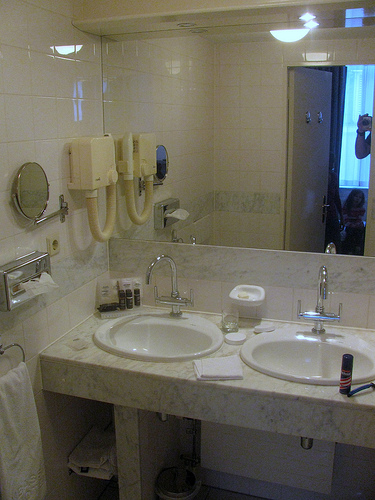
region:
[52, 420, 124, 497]
a folded towel on a shelf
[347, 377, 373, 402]
a blue razor on a bathroom counter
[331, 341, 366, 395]
a small container of shave cream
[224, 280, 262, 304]
a bar of soap in a soap dish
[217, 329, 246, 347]
a bar of soap on a bathroom counter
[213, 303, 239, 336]
a clear drinking glass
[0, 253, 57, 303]
a paper towel dispenser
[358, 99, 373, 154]
the reflection of someone holding a camera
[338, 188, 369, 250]
A little girls reflection in the mirror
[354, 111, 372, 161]
Reflection of someone holding a camera in the mirror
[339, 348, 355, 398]
Shaving cream on a bathroom sink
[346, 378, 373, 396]
Shaving blade on a bathroom sink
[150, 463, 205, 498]
Bucket under a bathroom sink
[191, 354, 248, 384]
Folded towel on a bathroom sink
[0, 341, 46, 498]
White hanging towel in a bathroom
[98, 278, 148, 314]
Toiletries on a bathroom sink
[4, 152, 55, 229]
Round mirror hanging on a wall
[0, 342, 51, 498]
White towel hanging on a holder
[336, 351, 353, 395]
Can of shaving cream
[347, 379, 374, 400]
Blue colored shaving cream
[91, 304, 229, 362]
Shiny reflective sink bowl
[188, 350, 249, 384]
Clean white folded towel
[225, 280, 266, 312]
Soap holder on a wall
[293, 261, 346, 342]
Shiny silver tap over the sink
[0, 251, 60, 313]
Tissue paper in a holder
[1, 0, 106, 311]
Reflective white tiled wall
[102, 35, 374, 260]
Clear mirror on a wall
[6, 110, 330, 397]
a bathroom with two sinks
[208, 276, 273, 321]
a soap dish on the wall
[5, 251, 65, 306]
the towels on the wall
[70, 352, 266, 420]
a marble counter top design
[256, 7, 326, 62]
a light on the ceiling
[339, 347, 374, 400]
items on the sink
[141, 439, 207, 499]
a garbage can underneath the sink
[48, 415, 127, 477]
a towel under the sink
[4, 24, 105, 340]
Shiny polished ceramic tiles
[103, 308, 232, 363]
Round shiny sink bowl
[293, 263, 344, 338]
Tap over the sink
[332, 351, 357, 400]
Can of shaving cream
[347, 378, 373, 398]
Blue colored shaving blade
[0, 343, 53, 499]
White towel on a rack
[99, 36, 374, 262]
Wide clear mirror with a reflection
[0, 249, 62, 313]
Tissue paper on a silver colored holder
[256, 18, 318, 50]
White light source on the roof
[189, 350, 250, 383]
Folded clean white towel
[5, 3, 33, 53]
a tile in a wall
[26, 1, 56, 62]
a tile in a wall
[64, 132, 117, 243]
cream colored wall mounted hair dryer unit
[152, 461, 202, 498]
small trashcan with plastic bag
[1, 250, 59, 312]
silver tissue paper holder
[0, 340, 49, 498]
white bath towel on silver hook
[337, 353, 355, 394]
navy blue shaving cream can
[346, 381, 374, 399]
black and blue disposable razor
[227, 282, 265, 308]
small piece of soap on white holder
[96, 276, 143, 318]
toiletries on top of tray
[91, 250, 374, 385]
two white sinks with silver faucets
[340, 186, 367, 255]
reflection of child in a mirror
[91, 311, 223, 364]
large white round sink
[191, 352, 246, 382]
small square cloth white rag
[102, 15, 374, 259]
large reflective square mirror